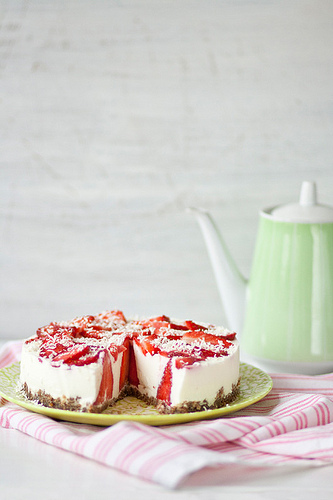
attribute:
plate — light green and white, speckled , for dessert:
[8, 366, 281, 427]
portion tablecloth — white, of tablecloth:
[178, 454, 203, 465]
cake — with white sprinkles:
[163, 339, 187, 353]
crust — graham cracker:
[157, 401, 210, 412]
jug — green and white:
[190, 181, 331, 379]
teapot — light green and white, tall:
[190, 180, 331, 371]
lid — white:
[261, 170, 331, 228]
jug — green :
[177, 198, 331, 385]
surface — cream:
[191, 366, 228, 398]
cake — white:
[17, 307, 242, 419]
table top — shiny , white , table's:
[6, 443, 48, 496]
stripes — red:
[263, 416, 284, 435]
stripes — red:
[287, 409, 309, 429]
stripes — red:
[201, 425, 228, 444]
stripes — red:
[311, 400, 330, 422]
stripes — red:
[242, 432, 258, 445]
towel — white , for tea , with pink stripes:
[0, 335, 333, 489]